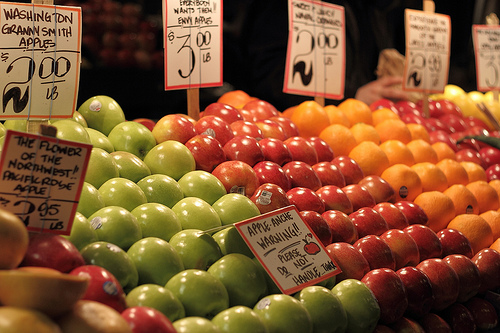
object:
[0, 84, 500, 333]
fruit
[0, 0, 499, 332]
stand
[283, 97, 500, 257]
oranges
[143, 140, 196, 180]
apples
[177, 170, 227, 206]
apples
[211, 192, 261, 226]
apples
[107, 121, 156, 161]
apples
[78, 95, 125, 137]
apples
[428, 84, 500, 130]
bananas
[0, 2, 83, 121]
paper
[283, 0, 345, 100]
sign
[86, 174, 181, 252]
smith apples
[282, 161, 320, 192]
red apple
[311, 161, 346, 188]
red apple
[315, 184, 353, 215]
red apple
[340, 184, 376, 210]
red apple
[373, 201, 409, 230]
red apple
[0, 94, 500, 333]
apple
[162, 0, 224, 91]
price sign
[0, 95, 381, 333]
apples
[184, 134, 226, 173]
apple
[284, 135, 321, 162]
apple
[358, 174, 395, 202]
apple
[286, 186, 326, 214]
apple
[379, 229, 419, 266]
apple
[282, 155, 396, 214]
red apples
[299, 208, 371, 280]
red apples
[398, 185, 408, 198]
sticker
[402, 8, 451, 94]
price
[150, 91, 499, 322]
pile